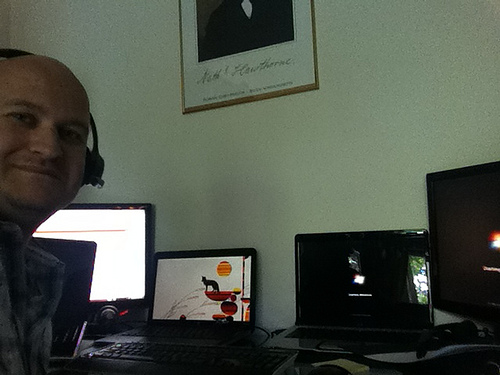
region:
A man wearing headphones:
[1, 43, 109, 224]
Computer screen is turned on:
[32, 203, 151, 306]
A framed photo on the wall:
[176, 0, 323, 122]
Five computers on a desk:
[28, 158, 498, 373]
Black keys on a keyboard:
[90, 338, 289, 372]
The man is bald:
[1, 52, 95, 219]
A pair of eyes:
[8, 106, 86, 149]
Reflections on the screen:
[340, 240, 433, 312]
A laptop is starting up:
[265, 223, 439, 363]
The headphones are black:
[1, 44, 108, 192]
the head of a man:
[5, 33, 187, 190]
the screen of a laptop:
[136, 233, 315, 333]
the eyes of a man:
[5, 87, 110, 147]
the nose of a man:
[23, 125, 86, 162]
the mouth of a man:
[12, 150, 107, 190]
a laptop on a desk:
[86, 220, 297, 372]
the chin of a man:
[5, 181, 77, 236]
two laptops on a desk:
[90, 176, 495, 361]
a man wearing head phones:
[6, 0, 151, 197]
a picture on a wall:
[137, 3, 369, 148]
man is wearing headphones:
[5, 32, 137, 239]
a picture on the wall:
[166, 7, 393, 138]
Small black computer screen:
[278, 216, 431, 326]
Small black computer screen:
[141, 243, 265, 324]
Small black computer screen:
[410, 159, 498, 316]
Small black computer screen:
[58, 192, 155, 317]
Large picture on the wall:
[161, 0, 342, 122]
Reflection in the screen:
[398, 236, 440, 316]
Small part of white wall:
[317, 163, 354, 234]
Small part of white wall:
[403, 53, 442, 101]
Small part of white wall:
[218, 125, 299, 205]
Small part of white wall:
[88, 29, 135, 78]